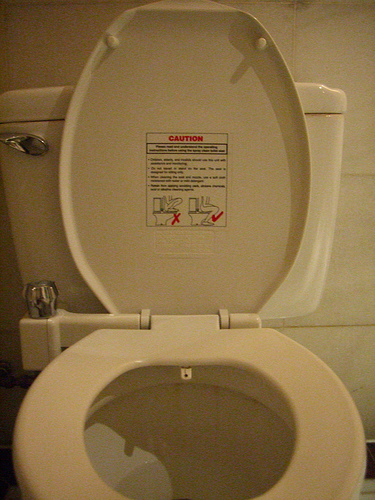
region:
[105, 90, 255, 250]
The toilet lid has text on it.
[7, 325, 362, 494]
The toilet seat is white.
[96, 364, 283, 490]
The toilet bowl has a shadow on the inside.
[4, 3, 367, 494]
The toilet is white.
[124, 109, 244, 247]
The caution sign on the toilet tells people sit.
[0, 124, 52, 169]
The flush knob on the toilet is metallic.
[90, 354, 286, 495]
The toilet bowl has water in it.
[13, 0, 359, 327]
The lid on the toilet is up.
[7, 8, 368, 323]
The wall behind the toilet is white.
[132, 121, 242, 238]
The sign says people cannot stand on the toilet.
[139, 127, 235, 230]
a sticker on the toilet lid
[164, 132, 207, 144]
red writing on the sticker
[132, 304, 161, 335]
a white hinge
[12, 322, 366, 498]
the seat of the toilet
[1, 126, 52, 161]
a metal flushing handle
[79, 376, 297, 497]
a shadow in the toilet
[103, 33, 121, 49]
a peg on the toilet lid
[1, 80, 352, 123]
the lid of the top of the toilet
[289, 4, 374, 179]
a white tile on the wall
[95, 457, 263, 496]
water in the toilet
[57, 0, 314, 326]
Toilet lid is up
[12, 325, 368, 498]
Round white toilet seat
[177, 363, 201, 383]
Small piece of metal sticking out on toilet seat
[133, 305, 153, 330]
Plastic hinge on toilet seat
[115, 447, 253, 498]
Water at the bottom of toilet bowl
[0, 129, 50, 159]
Chrome toilet flush handle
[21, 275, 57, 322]
Chrome knob on back right of toilet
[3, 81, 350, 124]
White ceramic toilet tank lid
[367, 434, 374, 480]
Brown floor and wall trim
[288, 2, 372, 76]
Yellow stained white tile on bathroom wall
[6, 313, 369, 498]
the seat of a toilet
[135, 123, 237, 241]
a sticker on the toilet id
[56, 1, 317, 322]
the lid of a toilet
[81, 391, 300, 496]
the shadow on the toilet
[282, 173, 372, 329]
a white tile on the wall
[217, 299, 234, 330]
a white hinge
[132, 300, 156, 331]
a toilet seat hinge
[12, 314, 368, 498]
a white toilet seat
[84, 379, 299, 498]
a shadow on the toilet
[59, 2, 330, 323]
the lid of the toilet